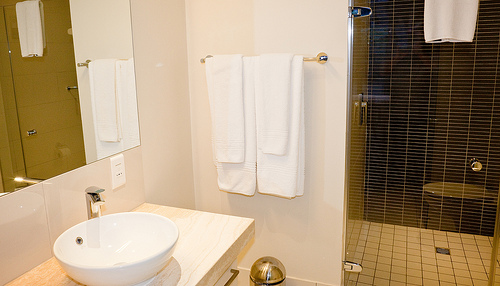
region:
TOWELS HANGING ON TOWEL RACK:
[198, 47, 315, 202]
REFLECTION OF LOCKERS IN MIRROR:
[2, 14, 89, 194]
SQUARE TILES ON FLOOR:
[346, 208, 495, 284]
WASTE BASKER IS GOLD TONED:
[243, 250, 294, 284]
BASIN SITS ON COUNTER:
[37, 205, 187, 283]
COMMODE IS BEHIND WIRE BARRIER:
[415, 166, 498, 228]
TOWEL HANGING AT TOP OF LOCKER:
[11, 1, 54, 62]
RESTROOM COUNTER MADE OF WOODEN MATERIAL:
[2, 197, 257, 284]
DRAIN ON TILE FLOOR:
[428, 236, 457, 262]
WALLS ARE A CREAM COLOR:
[3, 20, 345, 279]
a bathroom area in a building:
[27, 13, 497, 280]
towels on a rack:
[185, 42, 332, 207]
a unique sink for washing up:
[51, 185, 186, 270]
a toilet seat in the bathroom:
[400, 157, 495, 223]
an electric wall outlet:
[97, 155, 137, 187]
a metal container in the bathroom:
[237, 240, 292, 280]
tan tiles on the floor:
[347, 210, 494, 281]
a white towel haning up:
[10, 2, 60, 57]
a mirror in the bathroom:
[5, 4, 92, 192]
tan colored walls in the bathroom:
[151, 11, 217, 226]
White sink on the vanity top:
[54, 212, 186, 283]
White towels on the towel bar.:
[196, 42, 307, 203]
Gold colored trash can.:
[249, 251, 289, 283]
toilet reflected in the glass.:
[417, 169, 497, 240]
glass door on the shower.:
[341, 0, 498, 285]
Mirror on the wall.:
[0, 0, 168, 208]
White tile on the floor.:
[351, 210, 498, 283]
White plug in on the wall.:
[106, 150, 133, 194]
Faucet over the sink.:
[81, 179, 108, 223]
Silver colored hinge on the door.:
[339, 255, 367, 275]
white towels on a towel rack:
[195, 39, 330, 199]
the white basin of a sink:
[50, 210, 181, 278]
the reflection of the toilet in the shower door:
[422, 173, 487, 240]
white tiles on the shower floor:
[370, 236, 427, 278]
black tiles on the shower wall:
[398, 64, 476, 129]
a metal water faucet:
[77, 183, 111, 220]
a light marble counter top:
[177, 210, 233, 260]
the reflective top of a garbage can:
[248, 249, 287, 284]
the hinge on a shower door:
[341, 252, 365, 276]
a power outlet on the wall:
[107, 156, 127, 188]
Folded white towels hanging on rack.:
[205, 50, 315, 201]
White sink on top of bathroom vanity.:
[48, 204, 182, 284]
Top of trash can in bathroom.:
[247, 255, 291, 285]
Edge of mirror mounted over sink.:
[6, 3, 143, 193]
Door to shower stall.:
[341, 2, 499, 282]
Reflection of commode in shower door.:
[411, 174, 498, 233]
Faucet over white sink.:
[82, 183, 108, 219]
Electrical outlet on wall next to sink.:
[106, 151, 132, 193]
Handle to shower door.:
[349, 88, 373, 128]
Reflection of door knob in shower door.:
[464, 150, 486, 177]